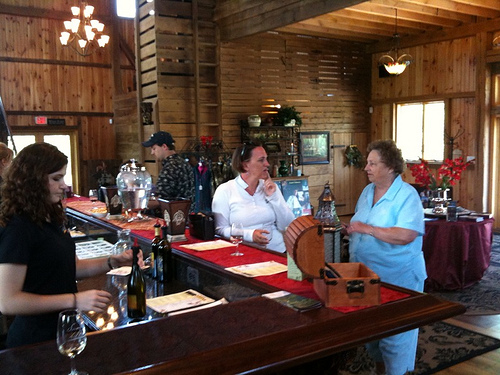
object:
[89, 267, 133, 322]
drink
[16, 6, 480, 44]
ceiling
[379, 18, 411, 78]
light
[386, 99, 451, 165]
window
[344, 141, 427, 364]
lady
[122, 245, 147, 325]
bottle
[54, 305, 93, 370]
glass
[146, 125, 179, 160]
head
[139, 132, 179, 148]
cap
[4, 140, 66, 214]
hair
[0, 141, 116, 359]
lady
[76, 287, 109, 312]
hand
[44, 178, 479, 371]
counter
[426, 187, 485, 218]
set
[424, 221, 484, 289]
table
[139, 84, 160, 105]
board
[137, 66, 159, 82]
board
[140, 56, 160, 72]
board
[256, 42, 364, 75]
wall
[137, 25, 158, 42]
board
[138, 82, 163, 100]
board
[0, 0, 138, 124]
wall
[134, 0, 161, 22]
board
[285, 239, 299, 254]
board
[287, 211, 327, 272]
wall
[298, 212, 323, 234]
board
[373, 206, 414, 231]
light blue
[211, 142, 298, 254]
woman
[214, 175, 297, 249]
shirt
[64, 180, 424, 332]
runner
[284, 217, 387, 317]
box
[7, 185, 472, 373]
counter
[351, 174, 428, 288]
shirt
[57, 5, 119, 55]
chandelier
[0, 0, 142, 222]
background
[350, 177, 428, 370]
outfit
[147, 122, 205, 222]
man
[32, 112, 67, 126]
sign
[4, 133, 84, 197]
door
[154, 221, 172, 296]
bottles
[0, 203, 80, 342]
shirt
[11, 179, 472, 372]
bar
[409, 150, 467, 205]
vase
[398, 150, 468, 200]
flowers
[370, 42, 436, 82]
fixture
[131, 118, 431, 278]
people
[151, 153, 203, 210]
shirt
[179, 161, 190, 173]
pattern